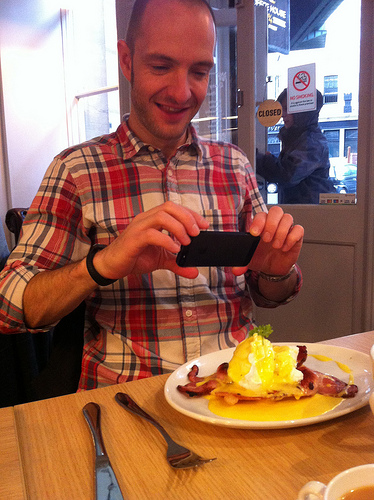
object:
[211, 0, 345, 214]
to enter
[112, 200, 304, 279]
cellphone hands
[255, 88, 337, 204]
woman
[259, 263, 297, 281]
watch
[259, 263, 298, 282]
wrist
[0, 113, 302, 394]
shirt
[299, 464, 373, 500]
coffee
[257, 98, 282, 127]
sign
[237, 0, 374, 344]
door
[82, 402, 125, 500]
butter knife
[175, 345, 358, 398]
bacon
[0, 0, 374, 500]
picture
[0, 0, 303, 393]
he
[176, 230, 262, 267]
phone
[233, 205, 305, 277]
hand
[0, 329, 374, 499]
table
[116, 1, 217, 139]
head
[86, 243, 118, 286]
wristband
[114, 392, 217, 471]
fork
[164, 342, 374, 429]
plate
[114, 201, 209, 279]
hands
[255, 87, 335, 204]
jacket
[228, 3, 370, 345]
doorway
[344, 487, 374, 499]
tea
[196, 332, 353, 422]
egg